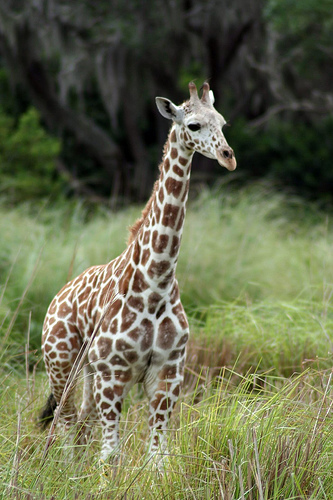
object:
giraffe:
[35, 76, 237, 495]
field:
[1, 188, 333, 500]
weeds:
[0, 190, 332, 365]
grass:
[0, 359, 333, 500]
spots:
[151, 229, 169, 255]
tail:
[36, 380, 57, 431]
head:
[156, 78, 238, 173]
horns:
[188, 81, 199, 101]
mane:
[124, 121, 173, 246]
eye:
[187, 123, 201, 133]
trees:
[237, 0, 315, 116]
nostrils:
[222, 150, 228, 157]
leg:
[91, 374, 127, 500]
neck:
[126, 124, 196, 294]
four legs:
[44, 355, 183, 497]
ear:
[156, 96, 178, 120]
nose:
[220, 146, 236, 159]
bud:
[0, 232, 22, 308]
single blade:
[291, 473, 295, 495]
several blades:
[220, 457, 226, 498]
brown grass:
[206, 417, 332, 499]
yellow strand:
[7, 399, 23, 487]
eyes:
[221, 122, 229, 134]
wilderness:
[1, 0, 333, 500]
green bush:
[0, 105, 67, 217]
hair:
[37, 390, 57, 434]